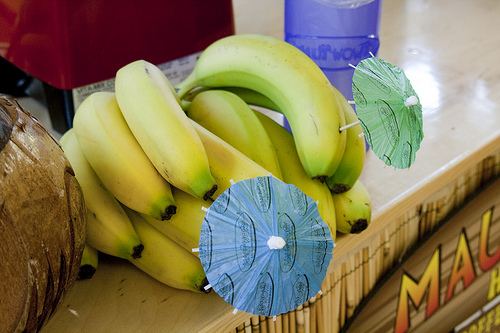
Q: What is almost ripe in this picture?
A: Bananas.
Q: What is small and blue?
A: A paper umbrella.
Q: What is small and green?
A: A paper umbrella.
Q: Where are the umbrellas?
A: Stuck on a bunch of bananas.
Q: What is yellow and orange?
A: The lettering.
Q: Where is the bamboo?
A: Along the edge of the table.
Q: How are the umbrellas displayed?
A: Sticking in the bananas.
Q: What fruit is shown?
A: Bananas.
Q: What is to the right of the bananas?
A: A blue tumbler.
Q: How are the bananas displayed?
A: On a counter.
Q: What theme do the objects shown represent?
A: Tropical.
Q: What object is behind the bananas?
A: The base of a blender.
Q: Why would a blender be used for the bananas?
A: Banana daiquiris.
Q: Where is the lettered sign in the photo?
A: In front of the table.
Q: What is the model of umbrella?
A: Cocktail.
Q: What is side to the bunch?
A: Water bottle.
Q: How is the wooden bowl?
A: Good.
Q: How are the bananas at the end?
A: Green.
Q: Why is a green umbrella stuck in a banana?
A: Makes the fruit look cute.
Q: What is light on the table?
A: Sunshine.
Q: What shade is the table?
A: Tan.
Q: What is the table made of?
A: Wood.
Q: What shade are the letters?
A: Yellow and orange.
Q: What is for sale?
A: Bananas.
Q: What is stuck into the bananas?
A: Blue umbrella.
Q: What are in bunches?
A: Bananas.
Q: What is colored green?
A: Bananas.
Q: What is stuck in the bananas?
A: Small umbrellas.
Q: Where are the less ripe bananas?
A: To the right.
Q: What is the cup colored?
A: Blue.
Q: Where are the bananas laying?
A: Table.